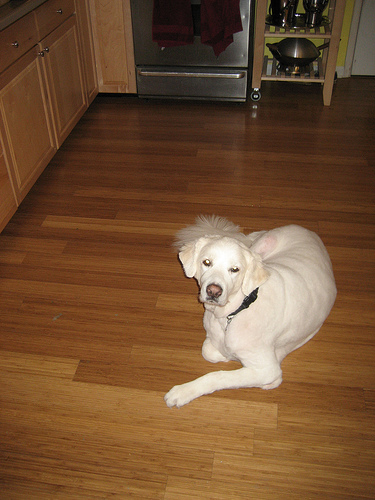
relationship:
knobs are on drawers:
[4, 0, 70, 56] [2, 0, 72, 64]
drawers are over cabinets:
[2, 0, 72, 64] [0, 17, 103, 235]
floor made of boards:
[4, 88, 373, 498] [97, 113, 303, 201]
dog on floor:
[156, 201, 346, 419] [4, 88, 373, 498]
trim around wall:
[343, 0, 368, 90] [256, 0, 363, 96]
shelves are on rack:
[263, 12, 331, 101] [255, 0, 345, 110]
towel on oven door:
[152, 2, 249, 57] [127, 0, 256, 117]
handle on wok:
[319, 38, 345, 54] [270, 40, 321, 70]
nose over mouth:
[198, 279, 230, 308] [197, 293, 224, 310]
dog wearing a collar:
[156, 201, 346, 419] [215, 275, 273, 317]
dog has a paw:
[156, 201, 346, 419] [156, 377, 210, 415]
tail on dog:
[173, 207, 275, 258] [156, 201, 346, 419]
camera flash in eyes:
[197, 257, 241, 284] [197, 254, 244, 285]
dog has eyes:
[156, 201, 346, 419] [197, 254, 244, 285]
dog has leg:
[156, 201, 346, 419] [244, 226, 297, 267]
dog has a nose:
[156, 201, 346, 419] [198, 279, 230, 308]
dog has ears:
[156, 201, 346, 419] [165, 234, 269, 294]